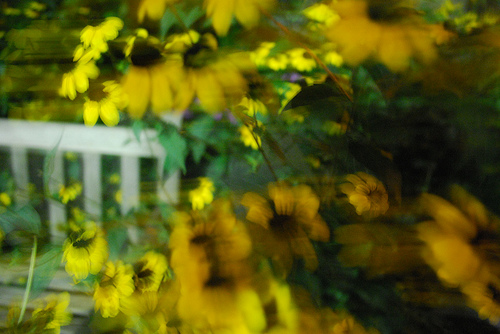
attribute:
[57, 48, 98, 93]
flower — yellow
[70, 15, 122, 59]
flower — yellow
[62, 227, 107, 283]
flower — yellow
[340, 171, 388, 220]
flower — yellow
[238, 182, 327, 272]
flower — yellow